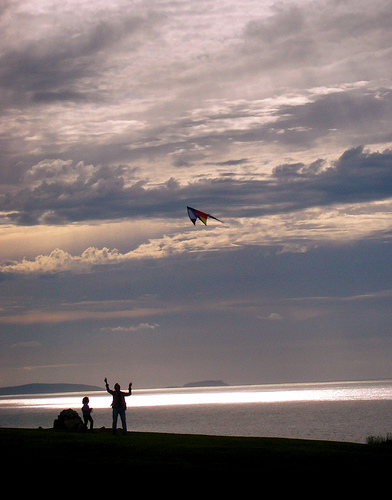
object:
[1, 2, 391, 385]
sky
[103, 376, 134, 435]
person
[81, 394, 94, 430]
person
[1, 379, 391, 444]
ocean water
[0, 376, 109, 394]
hill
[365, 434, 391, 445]
patch of grass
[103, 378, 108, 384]
hand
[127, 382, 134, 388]
hand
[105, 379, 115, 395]
arm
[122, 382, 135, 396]
arm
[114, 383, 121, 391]
head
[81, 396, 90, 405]
head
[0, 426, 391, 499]
beach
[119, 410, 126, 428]
leg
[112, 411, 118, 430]
leg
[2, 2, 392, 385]
clouds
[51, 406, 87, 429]
vegetation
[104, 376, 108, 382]
handle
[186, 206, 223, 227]
kite